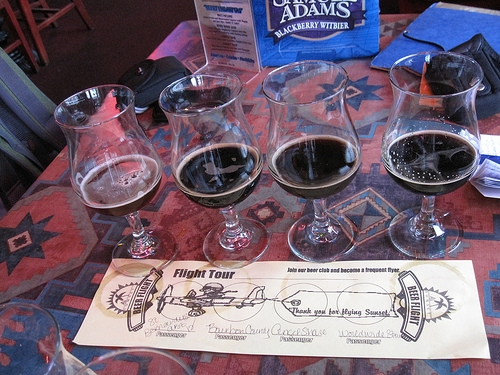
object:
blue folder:
[367, 0, 497, 80]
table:
[1, 10, 498, 375]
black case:
[419, 31, 498, 126]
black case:
[111, 53, 205, 126]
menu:
[72, 257, 492, 358]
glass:
[157, 68, 273, 271]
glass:
[378, 49, 485, 259]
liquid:
[271, 135, 358, 200]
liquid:
[173, 141, 263, 210]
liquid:
[80, 150, 162, 217]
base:
[284, 210, 355, 263]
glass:
[258, 59, 360, 264]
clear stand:
[195, 60, 255, 80]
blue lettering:
[203, 2, 242, 14]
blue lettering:
[209, 52, 255, 64]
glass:
[51, 84, 179, 277]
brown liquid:
[376, 127, 480, 199]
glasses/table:
[0, 15, 499, 375]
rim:
[273, 67, 279, 69]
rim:
[388, 50, 484, 99]